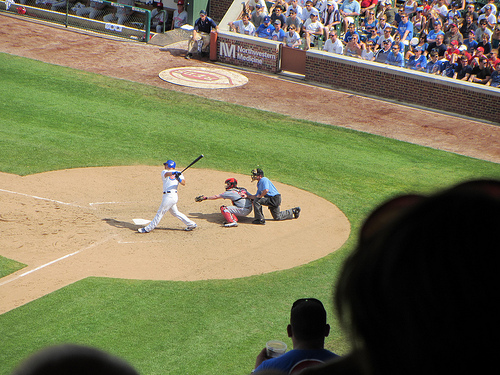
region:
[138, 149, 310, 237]
Three people playing baseball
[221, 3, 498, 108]
A crowd of people in the background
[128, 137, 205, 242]
Baseball player is holding a bat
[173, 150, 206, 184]
The bat is black in color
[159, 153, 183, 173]
Baseball player is wearing a helmet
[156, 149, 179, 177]
The helmet is blue in color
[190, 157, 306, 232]
A side view of two baseball catchers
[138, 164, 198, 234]
Baseball player is wearing a white outfit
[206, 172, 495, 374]
A back view of people's heads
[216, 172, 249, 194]
Catcher is wearing a red colored helmet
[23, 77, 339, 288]
it is a play ground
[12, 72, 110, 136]
green grass in the play ground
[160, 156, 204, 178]
man holding bat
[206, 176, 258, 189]
man wearing helmet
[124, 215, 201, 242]
man wearing shoe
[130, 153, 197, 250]
man wearing white dress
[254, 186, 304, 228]
man wearing black pant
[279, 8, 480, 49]
audience in the stadium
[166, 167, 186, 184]
man wearing hand glouse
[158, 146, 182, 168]
man wearing blue helmet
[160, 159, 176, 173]
batter has blue helmet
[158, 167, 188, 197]
batter has white shirt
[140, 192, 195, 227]
batter has white pants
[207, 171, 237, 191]
catcher has red mask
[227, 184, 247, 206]
catcher has grey shirt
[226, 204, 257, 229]
catcher has grey pants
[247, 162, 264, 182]
umpire has brown and black mask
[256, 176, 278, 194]
umpire has blue shirt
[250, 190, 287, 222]
umpire has grey pants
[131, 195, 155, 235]
home plate is white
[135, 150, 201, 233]
a baseball player with a bat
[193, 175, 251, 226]
a person crouching down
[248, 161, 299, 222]
a person kneeling down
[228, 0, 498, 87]
a crowd of people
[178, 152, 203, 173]
a black baseball bat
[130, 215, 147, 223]
the home base plate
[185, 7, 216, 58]
a person sitting down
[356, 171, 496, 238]
sunglasses on someone's head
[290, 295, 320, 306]
sunglasses on someone's head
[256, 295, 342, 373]
a person sitting in a crowd